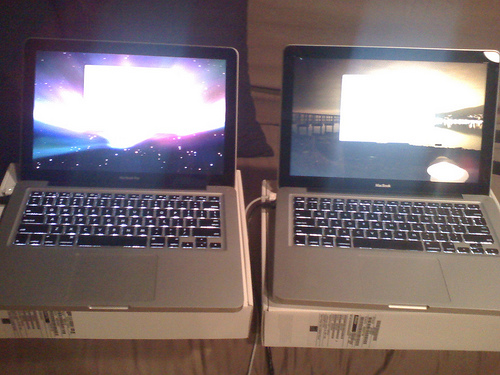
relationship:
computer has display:
[0, 35, 246, 314] [29, 52, 226, 174]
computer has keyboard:
[0, 35, 246, 314] [9, 183, 234, 260]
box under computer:
[0, 160, 255, 340] [0, 35, 246, 314]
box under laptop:
[257, 279, 498, 366] [271, 42, 498, 315]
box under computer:
[4, 294, 253, 342] [4, 47, 251, 315]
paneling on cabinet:
[131, 340, 203, 373] [0, 348, 499, 373]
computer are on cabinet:
[0, 35, 246, 314] [0, 348, 499, 373]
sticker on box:
[1, 308, 80, 338] [2, 155, 256, 342]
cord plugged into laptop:
[247, 187, 278, 212] [271, 42, 498, 315]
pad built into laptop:
[377, 250, 452, 305] [271, 42, 498, 315]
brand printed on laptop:
[374, 181, 391, 188] [271, 42, 498, 315]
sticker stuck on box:
[301, 309, 383, 354] [263, 307, 498, 365]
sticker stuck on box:
[1, 311, 91, 348] [8, 311, 262, 353]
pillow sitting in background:
[0, 2, 274, 160] [2, 1, 484, 187]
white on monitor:
[336, 54, 484, 161] [289, 55, 490, 183]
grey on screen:
[317, 138, 408, 169] [298, 100, 482, 150]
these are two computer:
[34, 51, 498, 375] [0, 35, 246, 314]